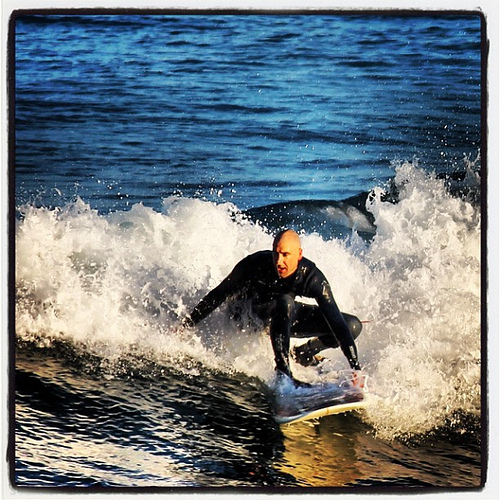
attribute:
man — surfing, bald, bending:
[183, 228, 364, 376]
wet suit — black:
[183, 250, 363, 372]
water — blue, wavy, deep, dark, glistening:
[14, 12, 481, 486]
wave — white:
[20, 138, 481, 445]